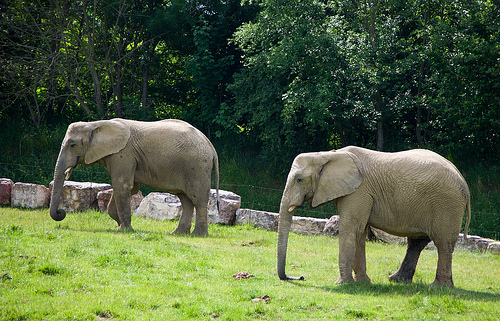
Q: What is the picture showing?
A: It is showing a field.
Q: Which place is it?
A: It is a field.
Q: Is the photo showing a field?
A: Yes, it is showing a field.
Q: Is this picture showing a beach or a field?
A: It is showing a field.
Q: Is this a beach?
A: No, it is a field.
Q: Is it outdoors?
A: Yes, it is outdoors.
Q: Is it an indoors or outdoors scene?
A: It is outdoors.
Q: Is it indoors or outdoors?
A: It is outdoors.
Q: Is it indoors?
A: No, it is outdoors.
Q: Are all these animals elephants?
A: Yes, all the animals are elephants.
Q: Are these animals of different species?
A: No, all the animals are elephants.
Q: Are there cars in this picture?
A: No, there are no cars.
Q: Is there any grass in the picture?
A: Yes, there is grass.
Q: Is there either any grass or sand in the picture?
A: Yes, there is grass.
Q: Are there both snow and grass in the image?
A: No, there is grass but no snow.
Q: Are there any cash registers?
A: No, there are no cash registers.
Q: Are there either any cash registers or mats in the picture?
A: No, there are no cash registers or mats.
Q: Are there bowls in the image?
A: No, there are no bowls.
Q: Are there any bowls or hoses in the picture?
A: No, there are no bowls or hoses.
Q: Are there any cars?
A: No, there are no cars.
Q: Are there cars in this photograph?
A: No, there are no cars.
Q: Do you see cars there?
A: No, there are no cars.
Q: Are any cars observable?
A: No, there are no cars.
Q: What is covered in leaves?
A: The trees are covered in leaves.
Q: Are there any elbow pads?
A: No, there are no elbow pads.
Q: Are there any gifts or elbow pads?
A: No, there are no elbow pads or gifts.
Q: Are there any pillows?
A: No, there are no pillows.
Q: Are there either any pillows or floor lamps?
A: No, there are no pillows or floor lamps.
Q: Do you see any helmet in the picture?
A: No, there are no helmets.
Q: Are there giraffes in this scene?
A: No, there are no giraffes.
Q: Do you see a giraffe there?
A: No, there are no giraffes.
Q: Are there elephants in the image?
A: Yes, there is an elephant.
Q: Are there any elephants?
A: Yes, there is an elephant.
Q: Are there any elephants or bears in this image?
A: Yes, there is an elephant.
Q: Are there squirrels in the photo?
A: No, there are no squirrels.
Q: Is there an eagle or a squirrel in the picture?
A: No, there are no squirrels or eagles.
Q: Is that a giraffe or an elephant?
A: That is an elephant.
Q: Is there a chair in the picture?
A: No, there are no chairs.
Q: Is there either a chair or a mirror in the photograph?
A: No, there are no chairs or mirrors.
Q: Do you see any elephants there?
A: Yes, there are elephants.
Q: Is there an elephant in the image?
A: Yes, there are elephants.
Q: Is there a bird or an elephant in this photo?
A: Yes, there are elephants.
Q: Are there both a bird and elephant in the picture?
A: No, there are elephants but no birds.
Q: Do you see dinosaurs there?
A: No, there are no dinosaurs.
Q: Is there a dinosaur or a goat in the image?
A: No, there are no dinosaurs or goats.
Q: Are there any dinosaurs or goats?
A: No, there are no dinosaurs or goats.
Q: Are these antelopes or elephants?
A: These are elephants.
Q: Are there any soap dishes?
A: No, there are no soap dishes.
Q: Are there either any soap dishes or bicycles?
A: No, there are no soap dishes or bicycles.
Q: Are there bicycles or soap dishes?
A: No, there are no soap dishes or bicycles.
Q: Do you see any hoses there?
A: No, there are no hoses.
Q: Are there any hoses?
A: No, there are no hoses.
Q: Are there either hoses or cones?
A: No, there are no hoses or cones.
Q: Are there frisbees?
A: No, there are no frisbees.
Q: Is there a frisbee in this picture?
A: No, there are no frisbees.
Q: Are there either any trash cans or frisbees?
A: No, there are no frisbees or trash cans.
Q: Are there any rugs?
A: No, there are no rugs.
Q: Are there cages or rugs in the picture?
A: No, there are no rugs or cages.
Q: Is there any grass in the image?
A: Yes, there is grass.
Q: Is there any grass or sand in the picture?
A: Yes, there is grass.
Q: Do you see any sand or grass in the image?
A: Yes, there is grass.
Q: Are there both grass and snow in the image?
A: No, there is grass but no snow.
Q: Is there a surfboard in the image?
A: No, there are no surfboards.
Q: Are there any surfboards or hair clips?
A: No, there are no surfboards or hair clips.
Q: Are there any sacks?
A: No, there are no sacks.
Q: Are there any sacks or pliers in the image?
A: No, there are no sacks or pliers.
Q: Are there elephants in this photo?
A: Yes, there is an elephant.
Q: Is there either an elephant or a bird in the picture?
A: Yes, there is an elephant.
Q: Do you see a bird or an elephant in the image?
A: Yes, there is an elephant.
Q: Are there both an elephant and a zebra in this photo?
A: No, there is an elephant but no zebras.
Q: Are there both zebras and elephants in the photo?
A: No, there is an elephant but no zebras.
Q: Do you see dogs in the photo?
A: No, there are no dogs.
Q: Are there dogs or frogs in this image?
A: No, there are no dogs or frogs.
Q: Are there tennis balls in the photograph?
A: No, there are no tennis balls.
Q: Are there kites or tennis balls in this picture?
A: No, there are no tennis balls or kites.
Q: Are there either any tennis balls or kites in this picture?
A: No, there are no tennis balls or kites.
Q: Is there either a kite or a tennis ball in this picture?
A: No, there are no tennis balls or kites.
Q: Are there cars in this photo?
A: No, there are no cars.